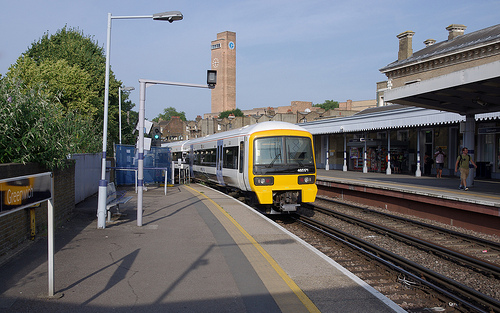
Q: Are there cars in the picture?
A: No, there are no cars.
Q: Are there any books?
A: No, there are no books.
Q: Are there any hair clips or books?
A: No, there are no books or hair clips.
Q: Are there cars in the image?
A: No, there are no cars.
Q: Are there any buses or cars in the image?
A: No, there are no cars or buses.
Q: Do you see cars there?
A: No, there are no cars.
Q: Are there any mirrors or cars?
A: No, there are no cars or mirrors.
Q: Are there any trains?
A: Yes, there is a train.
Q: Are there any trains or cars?
A: Yes, there is a train.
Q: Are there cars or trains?
A: Yes, there is a train.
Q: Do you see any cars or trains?
A: Yes, there is a train.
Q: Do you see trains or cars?
A: Yes, there is a train.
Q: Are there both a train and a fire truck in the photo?
A: No, there is a train but no fire trucks.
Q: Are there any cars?
A: No, there are no cars.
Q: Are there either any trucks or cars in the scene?
A: No, there are no cars or trucks.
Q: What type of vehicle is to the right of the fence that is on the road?
A: The vehicle is a train.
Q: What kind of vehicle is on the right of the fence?
A: The vehicle is a train.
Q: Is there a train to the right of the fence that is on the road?
A: Yes, there is a train to the right of the fence.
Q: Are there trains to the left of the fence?
A: No, the train is to the right of the fence.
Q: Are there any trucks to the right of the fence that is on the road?
A: No, there is a train to the right of the fence.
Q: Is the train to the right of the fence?
A: Yes, the train is to the right of the fence.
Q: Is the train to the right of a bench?
A: No, the train is to the right of the fence.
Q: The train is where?
A: The train is at the station.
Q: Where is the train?
A: The train is at the station.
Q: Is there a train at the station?
A: Yes, there is a train at the station.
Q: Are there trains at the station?
A: Yes, there is a train at the station.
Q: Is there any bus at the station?
A: No, there is a train at the station.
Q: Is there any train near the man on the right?
A: Yes, there is a train near the man.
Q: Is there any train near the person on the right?
A: Yes, there is a train near the man.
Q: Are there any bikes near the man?
A: No, there is a train near the man.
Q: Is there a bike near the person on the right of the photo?
A: No, there is a train near the man.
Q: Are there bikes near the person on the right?
A: No, there is a train near the man.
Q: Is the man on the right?
A: Yes, the man is on the right of the image.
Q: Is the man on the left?
A: No, the man is on the right of the image.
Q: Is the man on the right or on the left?
A: The man is on the right of the image.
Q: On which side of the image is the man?
A: The man is on the right of the image.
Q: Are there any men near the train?
A: Yes, there is a man near the train.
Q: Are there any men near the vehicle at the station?
A: Yes, there is a man near the train.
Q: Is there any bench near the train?
A: No, there is a man near the train.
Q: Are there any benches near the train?
A: No, there is a man near the train.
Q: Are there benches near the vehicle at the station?
A: No, there is a man near the train.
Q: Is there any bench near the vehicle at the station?
A: No, there is a man near the train.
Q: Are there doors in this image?
A: Yes, there is a door.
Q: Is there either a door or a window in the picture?
A: Yes, there is a door.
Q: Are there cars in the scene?
A: No, there are no cars.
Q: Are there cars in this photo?
A: No, there are no cars.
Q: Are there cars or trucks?
A: No, there are no cars or trucks.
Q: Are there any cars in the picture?
A: No, there are no cars.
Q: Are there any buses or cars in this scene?
A: No, there are no cars or buses.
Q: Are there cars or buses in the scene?
A: No, there are no cars or buses.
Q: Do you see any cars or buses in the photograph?
A: No, there are no cars or buses.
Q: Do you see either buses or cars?
A: No, there are no cars or buses.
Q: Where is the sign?
A: The sign is at the station.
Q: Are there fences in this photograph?
A: Yes, there is a fence.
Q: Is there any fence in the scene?
A: Yes, there is a fence.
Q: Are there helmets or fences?
A: Yes, there is a fence.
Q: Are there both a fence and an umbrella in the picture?
A: No, there is a fence but no umbrellas.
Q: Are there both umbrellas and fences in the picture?
A: No, there is a fence but no umbrellas.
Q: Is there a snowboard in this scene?
A: No, there are no snowboards.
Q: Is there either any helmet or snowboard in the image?
A: No, there are no snowboards or helmets.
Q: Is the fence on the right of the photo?
A: No, the fence is on the left of the image.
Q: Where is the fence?
A: The fence is on the road.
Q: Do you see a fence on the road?
A: Yes, there is a fence on the road.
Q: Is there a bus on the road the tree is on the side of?
A: No, there is a fence on the road.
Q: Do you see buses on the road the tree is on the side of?
A: No, there is a fence on the road.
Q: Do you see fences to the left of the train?
A: Yes, there is a fence to the left of the train.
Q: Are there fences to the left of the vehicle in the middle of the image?
A: Yes, there is a fence to the left of the train.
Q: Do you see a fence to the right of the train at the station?
A: No, the fence is to the left of the train.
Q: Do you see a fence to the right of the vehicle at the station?
A: No, the fence is to the left of the train.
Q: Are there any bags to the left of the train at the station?
A: No, there is a fence to the left of the train.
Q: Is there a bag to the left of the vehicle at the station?
A: No, there is a fence to the left of the train.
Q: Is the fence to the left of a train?
A: Yes, the fence is to the left of a train.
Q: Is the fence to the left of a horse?
A: No, the fence is to the left of a train.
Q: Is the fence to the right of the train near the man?
A: No, the fence is to the left of the train.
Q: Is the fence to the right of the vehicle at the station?
A: No, the fence is to the left of the train.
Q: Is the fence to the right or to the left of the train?
A: The fence is to the left of the train.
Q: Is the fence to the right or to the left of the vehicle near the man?
A: The fence is to the left of the train.